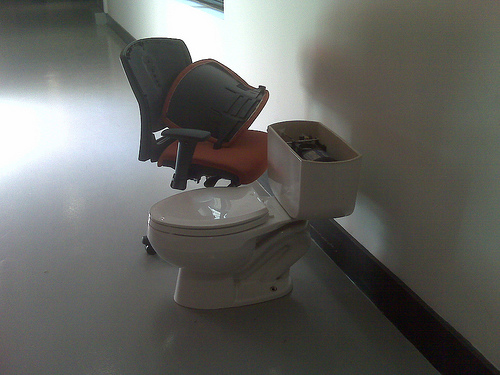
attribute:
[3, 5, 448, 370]
floor — bright white, white, grey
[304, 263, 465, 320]
floor — white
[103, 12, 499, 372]
trim — Black 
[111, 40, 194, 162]
chair — black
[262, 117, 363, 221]
holder — broken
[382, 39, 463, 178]
wall — white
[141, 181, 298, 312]
toilet seat — white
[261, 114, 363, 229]
toilet tank — white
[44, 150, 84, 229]
floor — slippery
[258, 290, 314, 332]
floor — white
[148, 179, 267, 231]
lid — covered, white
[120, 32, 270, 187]
seat — broken, orange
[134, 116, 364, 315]
toilet — white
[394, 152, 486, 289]
wall — white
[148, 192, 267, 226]
lid — white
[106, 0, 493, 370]
wall — white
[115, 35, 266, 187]
desk chair — black, red, broken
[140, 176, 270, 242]
lid — covered